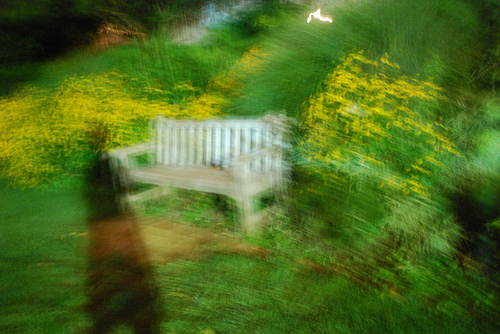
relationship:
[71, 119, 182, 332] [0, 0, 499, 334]
shadow on grass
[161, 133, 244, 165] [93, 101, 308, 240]
slats are on bench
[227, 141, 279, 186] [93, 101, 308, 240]
right arm on bench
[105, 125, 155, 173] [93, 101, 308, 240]
left arm on bench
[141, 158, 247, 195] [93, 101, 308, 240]
seat on bench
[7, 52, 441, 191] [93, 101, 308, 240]
flowers are around bench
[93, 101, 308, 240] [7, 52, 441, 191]
bench surrounded by flowers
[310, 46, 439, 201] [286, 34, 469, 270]
flowers are in a bush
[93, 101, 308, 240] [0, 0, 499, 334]
bench in grass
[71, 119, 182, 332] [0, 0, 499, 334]
shadow in grass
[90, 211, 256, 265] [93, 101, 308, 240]
dirt by bench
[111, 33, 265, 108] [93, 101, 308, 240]
grass behind bench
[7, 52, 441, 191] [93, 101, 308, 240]
flowers are by bench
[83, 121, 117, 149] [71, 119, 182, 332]
head on shadow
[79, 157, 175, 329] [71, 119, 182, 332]
bottom on shadow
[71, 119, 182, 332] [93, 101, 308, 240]
shadow by bench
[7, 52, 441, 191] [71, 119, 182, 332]
flowers are by shadow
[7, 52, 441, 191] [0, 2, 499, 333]
flowers are in garden